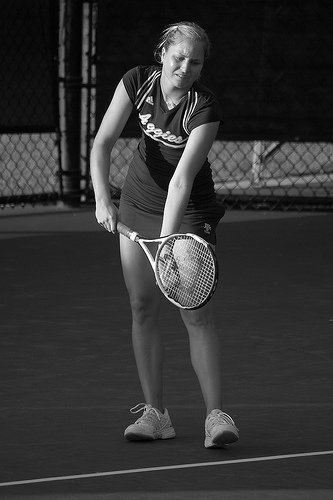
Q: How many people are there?
A: One.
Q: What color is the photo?
A: Black and white.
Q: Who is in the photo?
A: A lady.